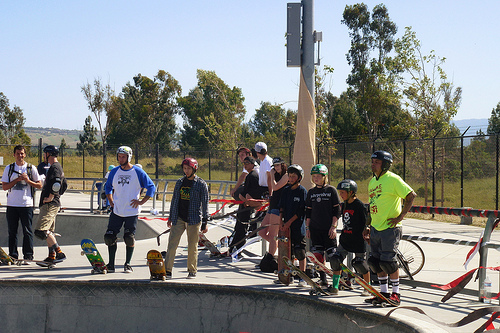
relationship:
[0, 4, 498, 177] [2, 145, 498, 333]
trees are standing behind park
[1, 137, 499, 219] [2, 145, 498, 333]
fence surrounding park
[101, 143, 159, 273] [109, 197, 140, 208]
skateboarder has hands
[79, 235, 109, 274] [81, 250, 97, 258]
skateboard has wheels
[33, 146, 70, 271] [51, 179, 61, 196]
person wearing pads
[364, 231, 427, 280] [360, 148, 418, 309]
bicycle standing behind people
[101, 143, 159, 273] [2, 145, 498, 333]
skateboarder standing at a park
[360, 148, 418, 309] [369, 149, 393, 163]
people wearing a helmet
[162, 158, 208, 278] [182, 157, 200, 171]
skater wearing a helmet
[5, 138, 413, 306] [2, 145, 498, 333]
group waiting at park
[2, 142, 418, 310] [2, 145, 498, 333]
people are in park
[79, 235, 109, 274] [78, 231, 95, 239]
skateboard pointing up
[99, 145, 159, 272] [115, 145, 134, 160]
man wearing a helmet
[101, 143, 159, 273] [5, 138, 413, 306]
skateboarder part of a group